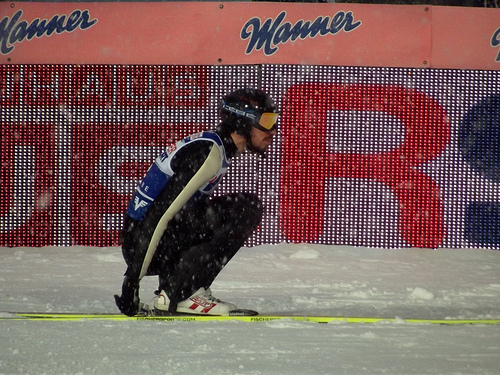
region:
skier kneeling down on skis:
[124, 75, 306, 310]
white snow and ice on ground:
[29, 243, 460, 373]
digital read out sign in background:
[22, 65, 493, 216]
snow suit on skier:
[100, 122, 265, 332]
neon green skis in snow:
[3, 307, 403, 327]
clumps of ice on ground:
[407, 287, 449, 314]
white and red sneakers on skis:
[166, 290, 247, 311]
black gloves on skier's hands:
[107, 290, 173, 321]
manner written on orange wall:
[247, 11, 376, 68]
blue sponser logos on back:
[135, 122, 216, 196]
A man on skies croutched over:
[1, 73, 497, 328]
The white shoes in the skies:
[151, 286, 239, 316]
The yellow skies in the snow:
[2, 309, 498, 326]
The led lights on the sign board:
[279, 67, 499, 250]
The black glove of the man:
[112, 281, 142, 318]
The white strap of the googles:
[219, 98, 257, 123]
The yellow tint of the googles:
[259, 111, 278, 128]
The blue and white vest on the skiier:
[122, 128, 229, 230]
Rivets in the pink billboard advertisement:
[215, 1, 227, 66]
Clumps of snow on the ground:
[285, 242, 476, 313]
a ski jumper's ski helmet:
[217, 88, 279, 135]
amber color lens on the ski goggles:
[218, 101, 280, 131]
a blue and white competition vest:
[125, 130, 222, 216]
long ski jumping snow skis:
[0, 313, 498, 325]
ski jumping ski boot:
[155, 286, 238, 314]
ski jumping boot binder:
[226, 306, 253, 316]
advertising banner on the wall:
[277, 0, 497, 245]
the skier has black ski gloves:
[112, 271, 137, 311]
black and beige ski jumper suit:
[120, 140, 260, 290]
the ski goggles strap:
[217, 100, 259, 121]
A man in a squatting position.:
[111, 85, 282, 317]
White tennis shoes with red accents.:
[154, 284, 236, 316]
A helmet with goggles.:
[220, 87, 279, 134]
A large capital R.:
[276, 76, 456, 251]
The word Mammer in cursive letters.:
[241, 3, 359, 60]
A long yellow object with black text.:
[2, 310, 497, 330]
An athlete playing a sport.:
[111, 85, 281, 319]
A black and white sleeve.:
[123, 137, 225, 284]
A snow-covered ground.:
[0, 240, 499, 373]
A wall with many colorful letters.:
[1, 65, 497, 249]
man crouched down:
[109, 85, 281, 322]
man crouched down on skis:
[0, 84, 498, 329]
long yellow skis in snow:
[5, 309, 499, 326]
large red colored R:
[275, 80, 450, 251]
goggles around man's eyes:
[217, 95, 279, 135]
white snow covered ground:
[0, 241, 497, 373]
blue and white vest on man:
[125, 127, 230, 232]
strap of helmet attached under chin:
[237, 130, 267, 162]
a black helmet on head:
[216, 87, 281, 163]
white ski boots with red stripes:
[155, 287, 240, 315]